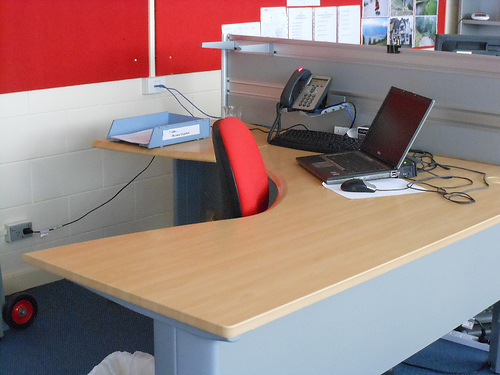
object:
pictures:
[363, 0, 439, 47]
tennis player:
[293, 79, 438, 191]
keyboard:
[321, 150, 387, 177]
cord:
[376, 148, 490, 205]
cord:
[250, 100, 357, 135]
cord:
[34, 156, 154, 233]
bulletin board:
[0, 0, 150, 96]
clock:
[471, 13, 489, 21]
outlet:
[146, 77, 167, 92]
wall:
[0, 2, 363, 296]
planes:
[106, 111, 208, 147]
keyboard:
[267, 126, 363, 154]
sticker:
[159, 124, 200, 140]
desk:
[18, 112, 498, 373]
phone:
[279, 68, 331, 112]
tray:
[106, 110, 208, 151]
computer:
[294, 86, 436, 185]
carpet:
[3, 277, 496, 375]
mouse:
[340, 178, 375, 194]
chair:
[209, 112, 274, 218]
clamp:
[386, 44, 397, 54]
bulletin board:
[220, 2, 366, 45]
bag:
[78, 348, 153, 373]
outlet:
[5, 222, 34, 242]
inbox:
[108, 111, 211, 148]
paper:
[111, 129, 152, 144]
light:
[296, 67, 304, 72]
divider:
[222, 30, 499, 165]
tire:
[2, 294, 40, 331]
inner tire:
[13, 302, 33, 322]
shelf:
[458, 17, 499, 28]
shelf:
[107, 110, 210, 150]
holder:
[107, 110, 211, 150]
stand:
[266, 104, 359, 155]